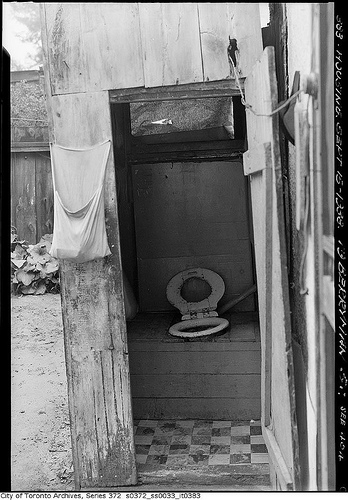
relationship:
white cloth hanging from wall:
[42, 130, 119, 268] [27, 8, 142, 480]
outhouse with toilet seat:
[39, 1, 300, 488] [164, 267, 229, 341]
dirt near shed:
[13, 388, 68, 445] [10, 225, 63, 467]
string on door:
[228, 52, 303, 117] [240, 44, 301, 491]